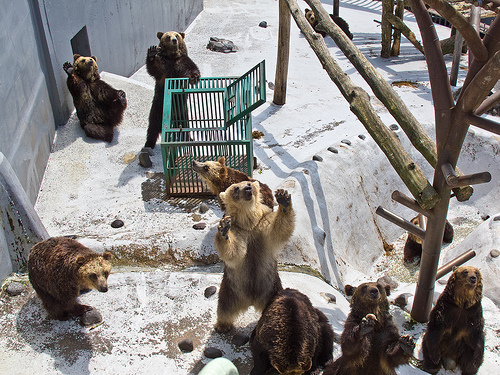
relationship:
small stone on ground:
[198, 30, 240, 65] [8, 0, 444, 373]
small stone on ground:
[374, 270, 410, 298] [8, 0, 444, 373]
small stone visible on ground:
[491, 244, 499, 262] [8, 0, 444, 373]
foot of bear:
[56, 57, 78, 83] [59, 48, 130, 147]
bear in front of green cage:
[177, 151, 287, 208] [148, 63, 274, 208]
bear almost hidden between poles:
[304, 10, 363, 50] [303, 0, 476, 253]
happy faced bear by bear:
[429, 256, 493, 374] [19, 211, 166, 318]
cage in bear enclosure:
[132, 30, 292, 217] [158, 65, 270, 204]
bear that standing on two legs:
[183, 162, 329, 331] [202, 177, 293, 325]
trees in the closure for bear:
[273, 0, 500, 302] [203, 165, 350, 355]